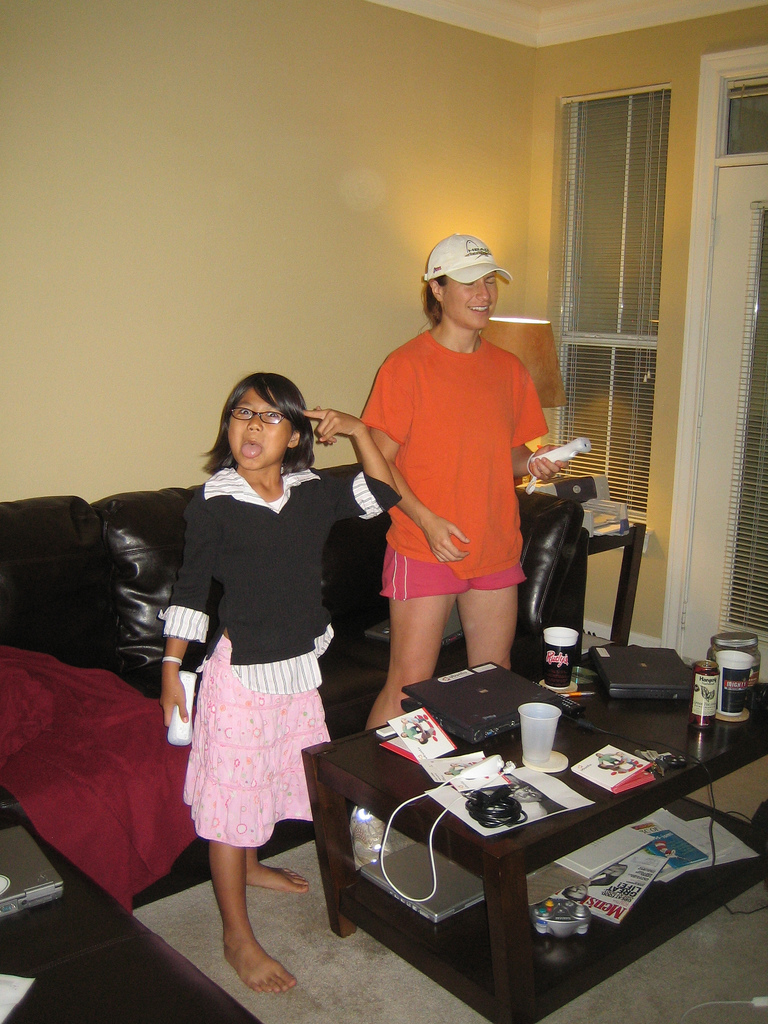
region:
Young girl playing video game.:
[155, 359, 341, 982]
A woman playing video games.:
[365, 233, 548, 724]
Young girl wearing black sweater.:
[153, 373, 353, 978]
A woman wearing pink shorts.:
[367, 242, 533, 735]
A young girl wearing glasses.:
[155, 357, 334, 984]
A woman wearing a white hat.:
[359, 218, 543, 768]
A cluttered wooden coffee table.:
[367, 622, 740, 959]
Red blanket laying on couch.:
[12, 641, 242, 933]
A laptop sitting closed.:
[0, 816, 59, 935]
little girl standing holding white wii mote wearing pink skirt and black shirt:
[157, 369, 402, 1002]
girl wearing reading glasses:
[219, 398, 302, 439]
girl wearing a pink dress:
[167, 633, 338, 859]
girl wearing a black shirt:
[161, 465, 400, 644]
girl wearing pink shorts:
[376, 542, 529, 599]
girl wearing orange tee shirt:
[362, 327, 574, 591]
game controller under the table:
[520, 884, 601, 943]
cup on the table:
[533, 619, 577, 711]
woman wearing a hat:
[407, 223, 518, 295]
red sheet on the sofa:
[20, 664, 205, 879]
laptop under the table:
[357, 841, 509, 926]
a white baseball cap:
[422, 233, 516, 293]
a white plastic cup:
[515, 699, 561, 757]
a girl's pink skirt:
[165, 615, 330, 853]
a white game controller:
[168, 657, 196, 744]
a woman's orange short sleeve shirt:
[358, 326, 551, 583]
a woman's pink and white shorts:
[370, 542, 527, 597]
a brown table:
[283, 665, 766, 1021]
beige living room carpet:
[138, 844, 764, 1022]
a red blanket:
[4, 588, 190, 916]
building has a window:
[558, 344, 610, 491]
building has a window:
[605, 347, 654, 513]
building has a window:
[620, 91, 673, 333]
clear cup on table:
[515, 697, 562, 763]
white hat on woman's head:
[428, 231, 513, 291]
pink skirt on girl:
[182, 631, 331, 849]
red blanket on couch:
[0, 642, 198, 916]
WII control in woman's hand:
[528, 433, 593, 480]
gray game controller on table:
[534, 889, 593, 944]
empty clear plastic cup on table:
[517, 698, 560, 767]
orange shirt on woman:
[360, 326, 552, 577]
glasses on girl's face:
[232, 401, 285, 428]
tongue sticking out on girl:
[237, 441, 263, 462]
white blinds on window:
[550, 93, 673, 536]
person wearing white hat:
[358, 234, 564, 735]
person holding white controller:
[358, 230, 571, 732]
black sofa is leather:
[0, 461, 590, 908]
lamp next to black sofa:
[475, 312, 568, 491]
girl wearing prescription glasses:
[226, 400, 290, 425]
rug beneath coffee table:
[129, 835, 765, 1021]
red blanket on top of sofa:
[0, 649, 202, 917]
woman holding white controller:
[532, 433, 592, 478]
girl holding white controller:
[166, 669, 195, 747]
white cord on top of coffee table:
[376, 777, 445, 905]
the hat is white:
[422, 233, 515, 285]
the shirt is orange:
[359, 329, 546, 584]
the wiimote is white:
[525, 433, 588, 493]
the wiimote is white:
[161, 653, 198, 746]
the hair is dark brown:
[202, 370, 315, 474]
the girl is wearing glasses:
[156, 373, 401, 990]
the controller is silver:
[533, 894, 591, 936]